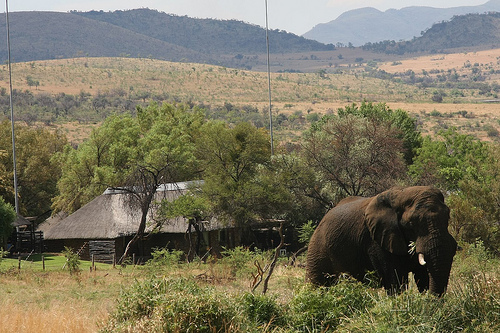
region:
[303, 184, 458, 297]
Large brown elephant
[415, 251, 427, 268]
One white elephant tusk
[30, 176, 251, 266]
Large brown hut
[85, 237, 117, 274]
Square wood on wood legs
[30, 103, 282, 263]
Large trees in front of a hut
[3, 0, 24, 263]
Large metal pole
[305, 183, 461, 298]
Elephant walking in a field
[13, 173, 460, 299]
Elephant walking away from a hut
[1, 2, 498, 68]
Four mountains in a mountain range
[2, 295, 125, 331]
Patch of dried grass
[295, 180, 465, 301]
Elephant is between the plants.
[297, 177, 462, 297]
Elephant is grey color.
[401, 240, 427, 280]
Tusk is white color.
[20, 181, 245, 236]
roof is grey color.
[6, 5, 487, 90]
Mountains are behind the elephant.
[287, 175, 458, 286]
Elephant has big ears.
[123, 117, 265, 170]
Leaves are green color.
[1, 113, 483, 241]
Trees are behind the elephant.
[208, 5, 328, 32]
Sky is white color.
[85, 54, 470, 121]
ground is brown color.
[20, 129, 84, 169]
green leaves in brown trees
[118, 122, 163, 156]
green leaves in brown trees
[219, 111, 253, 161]
green leaves in brown trees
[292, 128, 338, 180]
green leaves in brown trees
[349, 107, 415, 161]
green leaves in brown trees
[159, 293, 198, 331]
green leaves in brown bush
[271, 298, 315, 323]
green leaves in brown bush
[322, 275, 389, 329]
green leaves in brown bush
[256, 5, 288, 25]
white clouds in blue sky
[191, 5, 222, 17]
white clouds in blue sky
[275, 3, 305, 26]
white clouds in blue sky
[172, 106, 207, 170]
green leaves in brown trees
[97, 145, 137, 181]
green leaves in brown trees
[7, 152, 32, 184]
green leaves in brown trees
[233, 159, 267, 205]
green leaves in brown trees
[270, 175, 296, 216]
green leaves in brown trees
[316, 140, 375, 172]
green leaves in brown trees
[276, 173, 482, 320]
an elephant in grass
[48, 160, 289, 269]
a brown house by trees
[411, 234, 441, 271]
white tusk on elephant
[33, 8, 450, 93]
mountains in the distance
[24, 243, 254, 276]
a wood post fence with wire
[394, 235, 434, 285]
grass in mouth of elephant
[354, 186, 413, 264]
large ear of elephant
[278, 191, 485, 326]
a large brown elephant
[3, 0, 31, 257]
a large metal pole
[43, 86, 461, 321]
several trees around house